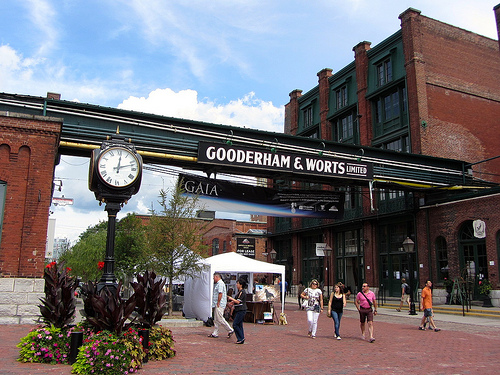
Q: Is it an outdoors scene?
A: Yes, it is outdoors.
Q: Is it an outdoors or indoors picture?
A: It is outdoors.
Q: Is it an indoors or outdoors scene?
A: It is outdoors.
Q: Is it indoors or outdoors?
A: It is outdoors.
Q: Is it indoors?
A: No, it is outdoors.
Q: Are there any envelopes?
A: No, there are no envelopes.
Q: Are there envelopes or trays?
A: No, there are no envelopes or trays.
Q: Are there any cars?
A: No, there are no cars.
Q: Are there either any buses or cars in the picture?
A: No, there are no cars or buses.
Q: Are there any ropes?
A: No, there are no ropes.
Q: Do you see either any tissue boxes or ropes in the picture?
A: No, there are no ropes or tissue boxes.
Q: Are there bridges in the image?
A: Yes, there is a bridge.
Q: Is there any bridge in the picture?
A: Yes, there is a bridge.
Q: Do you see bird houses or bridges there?
A: Yes, there is a bridge.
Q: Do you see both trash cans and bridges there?
A: No, there is a bridge but no trash cans.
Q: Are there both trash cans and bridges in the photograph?
A: No, there is a bridge but no trash cans.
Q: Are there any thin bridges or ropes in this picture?
A: Yes, there is a thin bridge.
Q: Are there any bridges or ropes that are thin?
A: Yes, the bridge is thin.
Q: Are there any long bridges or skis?
A: Yes, there is a long bridge.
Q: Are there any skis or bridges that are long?
A: Yes, the bridge is long.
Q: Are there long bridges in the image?
A: Yes, there is a long bridge.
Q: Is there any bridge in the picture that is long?
A: Yes, there is a bridge that is long.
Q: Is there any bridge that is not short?
A: Yes, there is a long bridge.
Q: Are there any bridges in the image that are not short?
A: Yes, there is a long bridge.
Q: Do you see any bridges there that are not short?
A: Yes, there is a long bridge.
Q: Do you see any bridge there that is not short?
A: Yes, there is a long bridge.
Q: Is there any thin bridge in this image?
A: Yes, there is a thin bridge.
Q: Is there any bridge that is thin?
A: Yes, there is a bridge that is thin.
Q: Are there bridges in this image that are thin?
A: Yes, there is a bridge that is thin.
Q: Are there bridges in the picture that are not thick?
A: Yes, there is a thin bridge.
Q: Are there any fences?
A: No, there are no fences.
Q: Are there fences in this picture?
A: No, there are no fences.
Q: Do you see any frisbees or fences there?
A: No, there are no fences or frisbees.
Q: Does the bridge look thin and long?
A: Yes, the bridge is thin and long.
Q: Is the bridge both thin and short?
A: No, the bridge is thin but long.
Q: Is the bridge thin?
A: Yes, the bridge is thin.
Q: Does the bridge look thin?
A: Yes, the bridge is thin.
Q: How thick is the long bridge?
A: The bridge is thin.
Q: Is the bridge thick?
A: No, the bridge is thin.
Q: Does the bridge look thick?
A: No, the bridge is thin.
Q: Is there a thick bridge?
A: No, there is a bridge but it is thin.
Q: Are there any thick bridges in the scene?
A: No, there is a bridge but it is thin.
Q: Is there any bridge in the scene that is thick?
A: No, there is a bridge but it is thin.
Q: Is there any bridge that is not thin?
A: No, there is a bridge but it is thin.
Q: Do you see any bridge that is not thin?
A: No, there is a bridge but it is thin.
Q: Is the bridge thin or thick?
A: The bridge is thin.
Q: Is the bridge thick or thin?
A: The bridge is thin.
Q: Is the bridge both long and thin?
A: Yes, the bridge is long and thin.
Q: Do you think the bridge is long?
A: Yes, the bridge is long.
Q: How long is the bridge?
A: The bridge is long.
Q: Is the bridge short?
A: No, the bridge is long.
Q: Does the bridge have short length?
A: No, the bridge is long.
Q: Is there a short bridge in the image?
A: No, there is a bridge but it is long.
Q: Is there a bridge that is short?
A: No, there is a bridge but it is long.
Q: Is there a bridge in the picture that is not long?
A: No, there is a bridge but it is long.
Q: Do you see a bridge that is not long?
A: No, there is a bridge but it is long.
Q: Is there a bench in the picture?
A: No, there are no benches.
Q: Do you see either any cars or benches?
A: No, there are no benches or cars.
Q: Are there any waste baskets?
A: No, there are no waste baskets.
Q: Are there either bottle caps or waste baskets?
A: No, there are no waste baskets or bottle caps.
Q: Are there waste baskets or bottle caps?
A: No, there are no waste baskets or bottle caps.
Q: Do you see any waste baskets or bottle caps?
A: No, there are no waste baskets or bottle caps.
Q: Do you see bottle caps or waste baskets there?
A: No, there are no waste baskets or bottle caps.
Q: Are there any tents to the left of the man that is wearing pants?
A: Yes, there is a tent to the left of the man.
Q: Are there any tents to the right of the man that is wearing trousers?
A: No, the tent is to the left of the man.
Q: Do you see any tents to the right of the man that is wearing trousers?
A: No, the tent is to the left of the man.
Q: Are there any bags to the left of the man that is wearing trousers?
A: No, there is a tent to the left of the man.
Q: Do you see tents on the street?
A: Yes, there is a tent on the street.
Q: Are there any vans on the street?
A: No, there is a tent on the street.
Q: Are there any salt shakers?
A: No, there are no salt shakers.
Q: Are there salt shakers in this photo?
A: No, there are no salt shakers.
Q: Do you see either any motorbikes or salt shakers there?
A: No, there are no salt shakers or motorbikes.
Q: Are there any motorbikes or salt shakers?
A: No, there are no salt shakers or motorbikes.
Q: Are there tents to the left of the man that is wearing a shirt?
A: Yes, there is a tent to the left of the man.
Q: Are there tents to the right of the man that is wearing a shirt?
A: No, the tent is to the left of the man.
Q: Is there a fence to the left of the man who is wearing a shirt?
A: No, there is a tent to the left of the man.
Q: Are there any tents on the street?
A: Yes, there is a tent on the street.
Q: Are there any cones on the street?
A: No, there is a tent on the street.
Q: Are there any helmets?
A: No, there are no helmets.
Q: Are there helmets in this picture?
A: No, there are no helmets.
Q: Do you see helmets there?
A: No, there are no helmets.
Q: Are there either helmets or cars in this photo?
A: No, there are no helmets or cars.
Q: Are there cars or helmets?
A: No, there are no helmets or cars.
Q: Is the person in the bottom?
A: Yes, the person is in the bottom of the image.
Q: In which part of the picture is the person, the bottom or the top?
A: The person is in the bottom of the image.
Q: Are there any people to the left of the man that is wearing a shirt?
A: Yes, there is a person to the left of the man.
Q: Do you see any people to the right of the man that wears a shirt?
A: No, the person is to the left of the man.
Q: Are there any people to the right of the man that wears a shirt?
A: No, the person is to the left of the man.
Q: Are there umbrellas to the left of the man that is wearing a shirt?
A: No, there is a person to the left of the man.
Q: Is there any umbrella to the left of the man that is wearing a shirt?
A: No, there is a person to the left of the man.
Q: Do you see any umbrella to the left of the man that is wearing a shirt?
A: No, there is a person to the left of the man.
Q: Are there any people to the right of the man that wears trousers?
A: Yes, there is a person to the right of the man.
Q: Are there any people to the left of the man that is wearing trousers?
A: No, the person is to the right of the man.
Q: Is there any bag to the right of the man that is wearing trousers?
A: No, there is a person to the right of the man.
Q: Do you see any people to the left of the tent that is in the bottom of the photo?
A: No, the person is to the right of the tent.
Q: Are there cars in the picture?
A: No, there are no cars.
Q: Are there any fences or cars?
A: No, there are no cars or fences.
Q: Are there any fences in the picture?
A: No, there are no fences.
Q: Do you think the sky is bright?
A: Yes, the sky is bright.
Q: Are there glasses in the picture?
A: No, there are no glasses.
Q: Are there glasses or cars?
A: No, there are no glasses or cars.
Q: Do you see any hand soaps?
A: No, there are no hand soaps.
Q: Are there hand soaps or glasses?
A: No, there are no hand soaps or glasses.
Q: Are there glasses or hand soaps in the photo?
A: No, there are no hand soaps or glasses.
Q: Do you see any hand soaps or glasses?
A: No, there are no hand soaps or glasses.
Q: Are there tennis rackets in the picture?
A: No, there are no tennis rackets.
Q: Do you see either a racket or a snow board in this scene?
A: No, there are no rackets or snowboards.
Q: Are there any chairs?
A: No, there are no chairs.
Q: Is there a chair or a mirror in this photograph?
A: No, there are no chairs or mirrors.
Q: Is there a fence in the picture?
A: No, there are no fences.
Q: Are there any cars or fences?
A: No, there are no fences or cars.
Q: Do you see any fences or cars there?
A: No, there are no fences or cars.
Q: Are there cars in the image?
A: No, there are no cars.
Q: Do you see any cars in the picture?
A: No, there are no cars.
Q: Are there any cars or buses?
A: No, there are no cars or buses.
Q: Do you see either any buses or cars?
A: No, there are no cars or buses.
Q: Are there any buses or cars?
A: No, there are no cars or buses.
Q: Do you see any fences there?
A: No, there are no fences.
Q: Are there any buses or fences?
A: No, there are no fences or buses.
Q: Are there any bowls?
A: No, there are no bowls.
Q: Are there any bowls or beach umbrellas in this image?
A: No, there are no bowls or beach umbrellas.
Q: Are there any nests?
A: No, there are no nests.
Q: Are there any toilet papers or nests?
A: No, there are no nests or toilet papers.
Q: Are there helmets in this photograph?
A: No, there are no helmets.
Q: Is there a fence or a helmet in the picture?
A: No, there are no helmets or fences.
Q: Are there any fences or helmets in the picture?
A: No, there are no helmets or fences.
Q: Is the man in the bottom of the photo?
A: Yes, the man is in the bottom of the image.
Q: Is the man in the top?
A: No, the man is in the bottom of the image.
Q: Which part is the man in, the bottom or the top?
A: The man is in the bottom of the image.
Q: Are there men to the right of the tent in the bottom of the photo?
A: Yes, there is a man to the right of the tent.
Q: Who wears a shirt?
A: The man wears a shirt.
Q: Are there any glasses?
A: No, there are no glasses.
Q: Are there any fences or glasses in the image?
A: No, there are no glasses or fences.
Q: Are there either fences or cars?
A: No, there are no fences or cars.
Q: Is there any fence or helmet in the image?
A: No, there are no fences or helmets.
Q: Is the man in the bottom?
A: Yes, the man is in the bottom of the image.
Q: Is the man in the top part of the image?
A: No, the man is in the bottom of the image.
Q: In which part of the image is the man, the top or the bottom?
A: The man is in the bottom of the image.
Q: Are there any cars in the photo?
A: No, there are no cars.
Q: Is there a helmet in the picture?
A: No, there are no helmets.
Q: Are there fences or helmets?
A: No, there are no helmets or fences.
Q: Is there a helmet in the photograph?
A: No, there are no helmets.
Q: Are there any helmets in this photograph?
A: No, there are no helmets.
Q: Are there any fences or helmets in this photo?
A: No, there are no helmets or fences.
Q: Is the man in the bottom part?
A: Yes, the man is in the bottom of the image.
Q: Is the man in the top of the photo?
A: No, the man is in the bottom of the image.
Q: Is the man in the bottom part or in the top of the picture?
A: The man is in the bottom of the image.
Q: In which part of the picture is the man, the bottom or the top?
A: The man is in the bottom of the image.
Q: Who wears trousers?
A: The man wears trousers.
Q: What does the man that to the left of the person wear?
A: The man wears trousers.